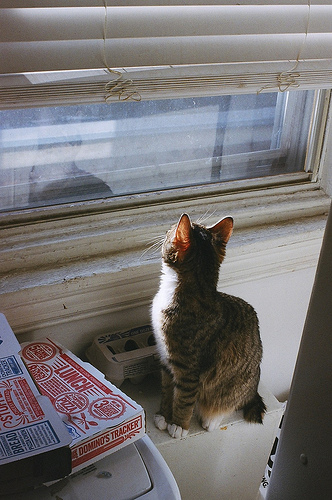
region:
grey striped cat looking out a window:
[146, 211, 283, 448]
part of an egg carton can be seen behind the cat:
[80, 310, 169, 390]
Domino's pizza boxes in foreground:
[1, 303, 146, 493]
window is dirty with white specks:
[109, 100, 283, 164]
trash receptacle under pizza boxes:
[21, 429, 185, 496]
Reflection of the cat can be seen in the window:
[25, 105, 119, 211]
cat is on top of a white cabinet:
[179, 436, 243, 482]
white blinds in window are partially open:
[0, 6, 328, 109]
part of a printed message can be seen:
[254, 408, 281, 499]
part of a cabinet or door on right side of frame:
[261, 202, 331, 496]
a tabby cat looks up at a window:
[149, 211, 266, 441]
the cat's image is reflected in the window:
[27, 107, 115, 206]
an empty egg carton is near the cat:
[84, 322, 163, 388]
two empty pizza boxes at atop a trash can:
[0, 312, 147, 499]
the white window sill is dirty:
[0, 181, 331, 333]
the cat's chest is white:
[150, 257, 181, 358]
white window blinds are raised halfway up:
[0, 0, 330, 110]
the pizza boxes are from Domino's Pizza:
[0, 312, 146, 495]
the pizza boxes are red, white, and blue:
[0, 312, 145, 493]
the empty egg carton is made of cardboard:
[84, 320, 158, 386]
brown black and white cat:
[154, 216, 264, 437]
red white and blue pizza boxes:
[2, 314, 147, 491]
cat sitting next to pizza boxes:
[0, 212, 267, 482]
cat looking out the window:
[3, 6, 331, 437]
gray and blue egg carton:
[81, 327, 154, 380]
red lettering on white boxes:
[1, 319, 145, 486]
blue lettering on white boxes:
[0, 314, 146, 483]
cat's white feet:
[156, 413, 225, 438]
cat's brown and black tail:
[244, 398, 264, 424]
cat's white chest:
[151, 263, 180, 365]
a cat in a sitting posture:
[138, 209, 271, 436]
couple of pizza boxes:
[0, 302, 150, 495]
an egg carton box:
[79, 303, 162, 394]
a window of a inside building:
[0, 79, 329, 225]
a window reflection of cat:
[3, 105, 127, 204]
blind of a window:
[1, 0, 330, 110]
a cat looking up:
[145, 205, 269, 438]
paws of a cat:
[152, 400, 196, 445]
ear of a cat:
[171, 209, 235, 250]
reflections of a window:
[2, 101, 312, 207]